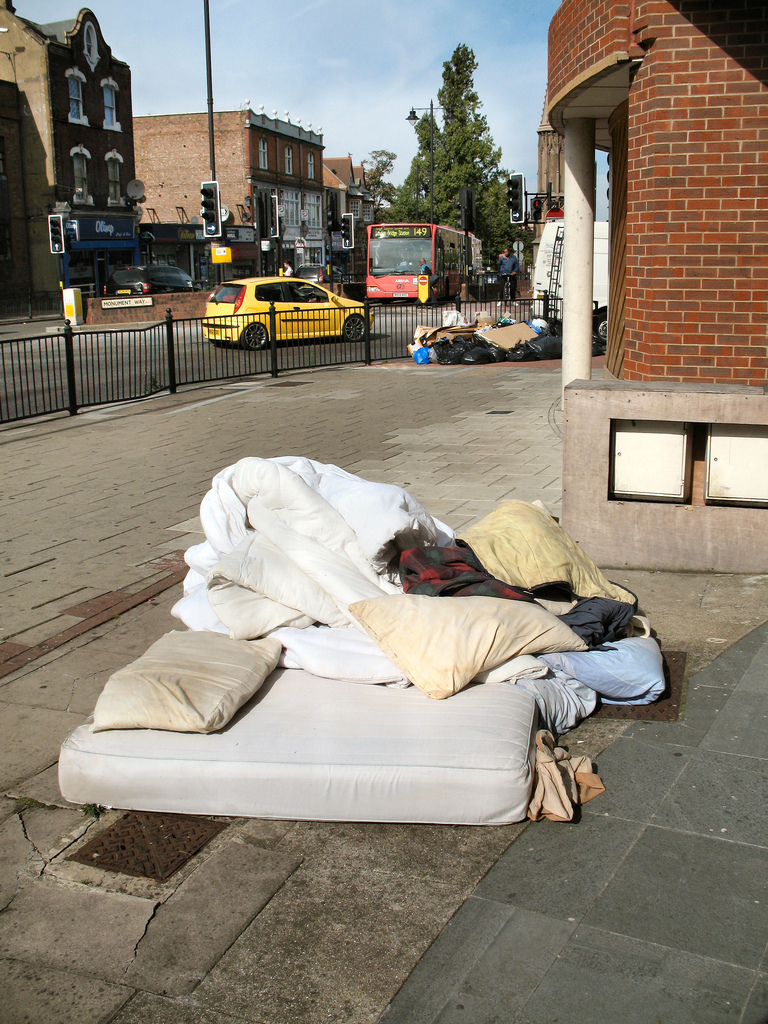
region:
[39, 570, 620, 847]
THE MATTRESS IS ON THE SIDEWALK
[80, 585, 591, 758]
THE PILLOWS ARE ON THE MATTRESS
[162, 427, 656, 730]
THE BLANKETS ARE ON THE MATTRESS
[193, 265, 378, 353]
THE CAR IS YELLOW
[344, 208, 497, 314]
THE BUS IS RED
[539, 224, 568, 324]
THE LADDER IS ON THE VAN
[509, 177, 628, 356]
THE VAN IS WHITE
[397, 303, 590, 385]
THE GARBAGE IS ON THE SIDEWALK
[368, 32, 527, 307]
THE TREE IS TALL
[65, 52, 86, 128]
a window on a building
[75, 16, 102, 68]
a window on a building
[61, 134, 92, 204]
a window on a building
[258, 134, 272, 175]
a window on a building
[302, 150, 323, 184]
a window on a building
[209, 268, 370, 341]
a car on a street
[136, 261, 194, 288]
a car on a street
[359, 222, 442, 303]
A red and yellow bus front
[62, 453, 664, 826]
A mattress, pillow and cover on the street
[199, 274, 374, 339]
A small yellow car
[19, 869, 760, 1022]
A gray brick sidewalk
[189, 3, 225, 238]
A street light on a pole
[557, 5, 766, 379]
A red brick building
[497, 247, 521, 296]
A man in a blue shirt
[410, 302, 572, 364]
A pile of trash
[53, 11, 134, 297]
A building with a blue store front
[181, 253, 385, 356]
a small car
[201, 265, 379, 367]
a small yellow car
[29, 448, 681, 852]
a mattress and pile of blankets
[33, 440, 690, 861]
mattress on the street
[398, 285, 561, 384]
a pile of trassh bags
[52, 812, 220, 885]
a rusty sewer drain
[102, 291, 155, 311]
a white sign on wall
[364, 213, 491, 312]
a large red bus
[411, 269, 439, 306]
a yellow and red sign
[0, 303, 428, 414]
a black iron fence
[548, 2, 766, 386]
well constructed brick building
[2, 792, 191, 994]
Broken sidewalk concrete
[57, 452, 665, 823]
old mattress, covers, and pillows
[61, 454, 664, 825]
trash littering the city sidewalk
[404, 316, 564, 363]
garbage piling up along the sidewalk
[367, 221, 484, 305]
commuter bus waiting on customers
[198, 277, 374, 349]
yellow cab making a right hand turn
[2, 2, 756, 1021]
view taken at the coner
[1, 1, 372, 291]
city buildings and businesses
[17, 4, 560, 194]
A bluish grey sky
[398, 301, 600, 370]
A pile of trash on the sidewalk.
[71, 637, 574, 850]
An old mattress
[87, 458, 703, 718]
A pile of blankets and pillows outside on the cement.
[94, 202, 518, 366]
Vehicles on the road.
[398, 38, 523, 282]
A green leafy tree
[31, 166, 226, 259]
Traffic lights hanging on poles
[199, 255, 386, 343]
A yellow two door car.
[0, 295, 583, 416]
A black fence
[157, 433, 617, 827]
bedding piled on street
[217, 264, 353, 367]
yellow car on road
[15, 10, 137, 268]
brown and white building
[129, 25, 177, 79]
white clouds in blue sky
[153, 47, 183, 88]
white clouds in blue sky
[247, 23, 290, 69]
white clouds in blue sky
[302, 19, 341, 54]
white clouds in blue sky